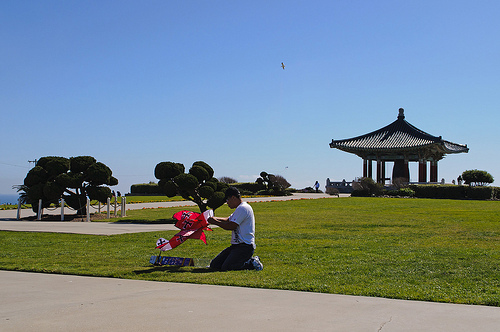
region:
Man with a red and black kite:
[164, 177, 272, 279]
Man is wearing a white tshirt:
[213, 185, 266, 245]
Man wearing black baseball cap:
[213, 189, 250, 219]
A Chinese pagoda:
[328, 98, 470, 201]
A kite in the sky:
[258, 46, 298, 79]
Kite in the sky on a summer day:
[241, 25, 310, 108]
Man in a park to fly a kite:
[44, 142, 301, 301]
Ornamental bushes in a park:
[18, 137, 126, 222]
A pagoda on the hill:
[287, 32, 467, 218]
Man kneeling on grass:
[178, 185, 270, 287]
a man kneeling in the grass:
[57, 138, 345, 305]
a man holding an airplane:
[139, 156, 305, 283]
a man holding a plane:
[122, 159, 265, 284]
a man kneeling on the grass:
[139, 158, 293, 283]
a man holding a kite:
[132, 167, 318, 280]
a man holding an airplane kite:
[129, 148, 293, 290]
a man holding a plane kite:
[91, 129, 298, 288]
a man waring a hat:
[189, 168, 290, 275]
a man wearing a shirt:
[190, 186, 286, 273]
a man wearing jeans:
[179, 171, 284, 274]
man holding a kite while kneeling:
[206, 185, 263, 268]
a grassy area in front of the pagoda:
[0, 194, 499, 307]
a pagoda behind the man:
[329, 108, 469, 188]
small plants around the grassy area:
[20, 150, 499, 214]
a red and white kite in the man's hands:
[153, 208, 217, 250]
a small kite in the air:
[280, 61, 286, 69]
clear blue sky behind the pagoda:
[0, 0, 499, 204]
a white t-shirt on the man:
[229, 201, 255, 248]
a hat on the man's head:
[221, 187, 239, 198]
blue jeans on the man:
[210, 240, 254, 268]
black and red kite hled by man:
[160, 203, 218, 245]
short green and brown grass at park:
[286, 211, 318, 238]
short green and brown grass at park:
[274, 222, 311, 256]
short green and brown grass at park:
[295, 249, 352, 275]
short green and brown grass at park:
[9, 231, 51, 255]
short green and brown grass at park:
[84, 249, 126, 271]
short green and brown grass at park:
[376, 252, 422, 276]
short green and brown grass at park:
[424, 202, 498, 256]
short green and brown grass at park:
[321, 202, 384, 240]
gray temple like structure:
[361, 114, 441, 193]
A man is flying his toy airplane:
[135, 172, 277, 277]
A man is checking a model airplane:
[135, 166, 276, 277]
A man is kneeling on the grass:
[130, 175, 285, 275]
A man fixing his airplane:
[137, 180, 267, 276]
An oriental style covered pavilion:
[325, 76, 470, 177]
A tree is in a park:
[15, 150, 131, 225]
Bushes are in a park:
[415, 180, 490, 201]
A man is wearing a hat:
[218, 184, 241, 205]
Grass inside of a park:
[307, 205, 413, 270]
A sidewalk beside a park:
[20, 283, 133, 325]